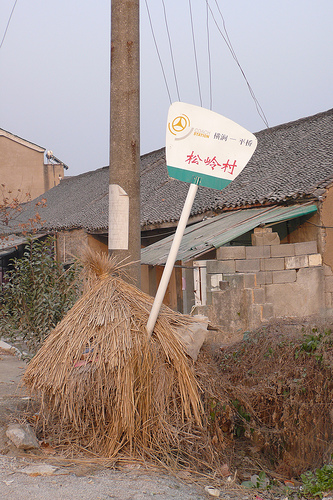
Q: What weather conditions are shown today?
A: It is clear.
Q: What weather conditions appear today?
A: It is clear.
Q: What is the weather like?
A: It is clear.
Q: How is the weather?
A: It is clear.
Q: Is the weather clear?
A: Yes, it is clear.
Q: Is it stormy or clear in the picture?
A: It is clear.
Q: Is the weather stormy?
A: No, it is clear.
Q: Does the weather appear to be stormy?
A: No, it is clear.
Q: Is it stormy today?
A: No, it is clear.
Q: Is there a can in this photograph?
A: No, there are no cans.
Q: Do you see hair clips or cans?
A: No, there are no cans or hair clips.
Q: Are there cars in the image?
A: No, there are no cars.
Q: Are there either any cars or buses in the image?
A: No, there are no cars or buses.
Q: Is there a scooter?
A: No, there are no scooters.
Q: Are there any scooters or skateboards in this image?
A: No, there are no scooters or skateboards.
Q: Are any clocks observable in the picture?
A: No, there are no clocks.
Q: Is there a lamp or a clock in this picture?
A: No, there are no clocks or lamps.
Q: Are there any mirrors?
A: No, there are no mirrors.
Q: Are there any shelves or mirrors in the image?
A: No, there are no mirrors or shelves.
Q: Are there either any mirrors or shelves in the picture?
A: No, there are no mirrors or shelves.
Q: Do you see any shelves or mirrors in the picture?
A: No, there are no mirrors or shelves.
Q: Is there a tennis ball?
A: No, there are no tennis balls.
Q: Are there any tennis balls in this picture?
A: No, there are no tennis balls.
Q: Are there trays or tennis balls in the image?
A: No, there are no tennis balls or trays.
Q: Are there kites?
A: No, there are no kites.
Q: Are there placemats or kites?
A: No, there are no kites or placemats.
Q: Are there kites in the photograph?
A: No, there are no kites.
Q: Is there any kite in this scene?
A: No, there are no kites.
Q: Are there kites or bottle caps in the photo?
A: No, there are no kites or bottle caps.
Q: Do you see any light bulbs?
A: No, there are no light bulbs.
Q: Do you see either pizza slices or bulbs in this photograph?
A: No, there are no bulbs or pizza slices.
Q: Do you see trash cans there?
A: No, there are no trash cans.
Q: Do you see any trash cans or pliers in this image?
A: No, there are no trash cans or pliers.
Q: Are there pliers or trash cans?
A: No, there are no trash cans or pliers.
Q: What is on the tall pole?
A: The paper is on the pole.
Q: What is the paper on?
A: The paper is on the pole.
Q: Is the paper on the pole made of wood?
A: Yes, the paper is on the pole.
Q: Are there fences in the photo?
A: No, there are no fences.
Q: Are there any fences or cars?
A: No, there are no fences or cars.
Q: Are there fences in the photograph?
A: No, there are no fences.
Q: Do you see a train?
A: No, there are no trains.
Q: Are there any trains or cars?
A: No, there are no trains or cars.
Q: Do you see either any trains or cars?
A: No, there are no trains or cars.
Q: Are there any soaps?
A: No, there are no soaps.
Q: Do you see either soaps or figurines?
A: No, there are no soaps or figurines.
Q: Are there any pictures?
A: No, there are no pictures.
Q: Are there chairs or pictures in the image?
A: No, there are no pictures or chairs.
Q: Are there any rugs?
A: No, there are no rugs.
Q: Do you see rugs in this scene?
A: No, there are no rugs.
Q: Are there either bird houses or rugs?
A: No, there are no rugs or bird houses.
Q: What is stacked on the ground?
A: The straw is stacked on the ground.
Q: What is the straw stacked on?
A: The straw is stacked on the ground.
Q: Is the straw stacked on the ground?
A: Yes, the straw is stacked on the ground.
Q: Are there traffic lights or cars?
A: No, there are no cars or traffic lights.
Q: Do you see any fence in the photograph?
A: No, there are no fences.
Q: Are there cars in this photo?
A: No, there are no cars.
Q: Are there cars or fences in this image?
A: No, there are no cars or fences.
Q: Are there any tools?
A: No, there are no tools.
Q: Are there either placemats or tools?
A: No, there are no tools or placemats.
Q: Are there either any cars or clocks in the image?
A: No, there are no cars or clocks.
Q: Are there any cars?
A: No, there are no cars.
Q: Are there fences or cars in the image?
A: No, there are no cars or fences.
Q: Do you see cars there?
A: No, there are no cars.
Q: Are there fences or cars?
A: No, there are no cars or fences.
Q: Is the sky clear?
A: Yes, the sky is clear.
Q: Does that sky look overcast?
A: No, the sky is clear.